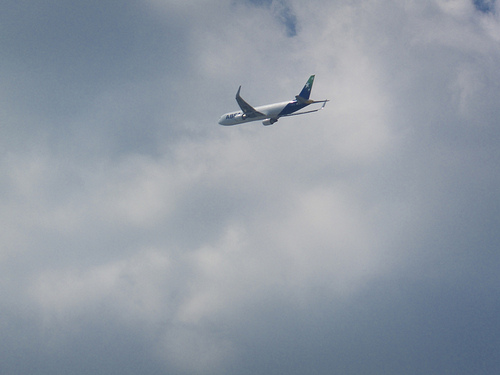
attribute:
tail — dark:
[293, 73, 331, 105]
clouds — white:
[0, 0, 499, 374]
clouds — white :
[48, 12, 424, 352]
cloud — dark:
[319, 227, 473, 337]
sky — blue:
[9, 14, 458, 317]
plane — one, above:
[216, 75, 326, 130]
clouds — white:
[186, 127, 328, 237]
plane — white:
[210, 72, 344, 132]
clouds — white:
[76, 160, 391, 293]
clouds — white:
[313, 20, 464, 150]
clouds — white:
[342, 49, 467, 203]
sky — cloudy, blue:
[2, 1, 499, 373]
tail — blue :
[293, 70, 316, 105]